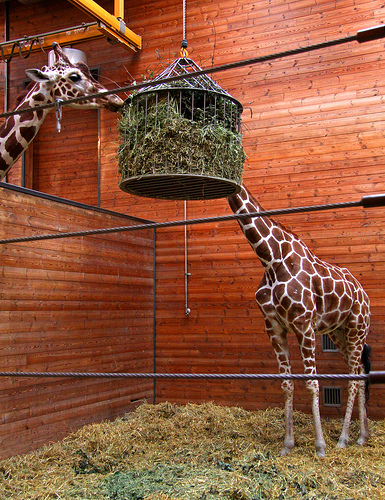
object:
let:
[0, 370, 385, 385]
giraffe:
[0, 43, 126, 181]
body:
[227, 186, 369, 455]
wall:
[0, 191, 156, 460]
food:
[117, 75, 245, 179]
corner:
[139, 225, 172, 414]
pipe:
[5, 12, 12, 111]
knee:
[279, 362, 294, 393]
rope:
[181, 0, 186, 43]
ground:
[0, 402, 385, 500]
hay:
[0, 398, 385, 499]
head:
[25, 41, 124, 114]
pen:
[0, 24, 385, 386]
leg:
[260, 303, 296, 451]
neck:
[0, 79, 53, 179]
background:
[0, 0, 385, 499]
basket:
[117, 58, 243, 196]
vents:
[20, 149, 26, 187]